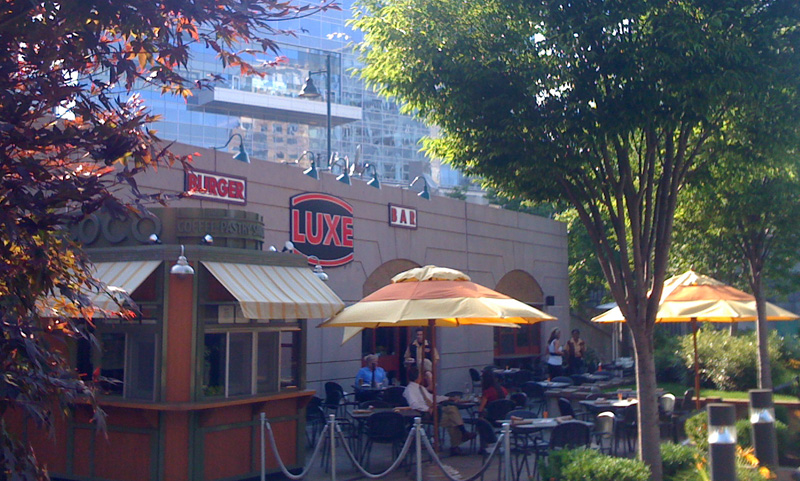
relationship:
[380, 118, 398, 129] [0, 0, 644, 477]
window on building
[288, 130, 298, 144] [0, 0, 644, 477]
window on building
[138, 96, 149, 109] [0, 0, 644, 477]
window on building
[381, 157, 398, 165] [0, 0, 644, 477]
window on building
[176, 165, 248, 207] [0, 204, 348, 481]
sign on small building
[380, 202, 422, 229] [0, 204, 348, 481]
sign on small building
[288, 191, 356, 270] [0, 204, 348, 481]
luxe sign on small building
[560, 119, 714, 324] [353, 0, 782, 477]
branches are on tree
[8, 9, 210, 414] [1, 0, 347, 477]
leaves are on tree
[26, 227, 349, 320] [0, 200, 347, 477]
awnings on small building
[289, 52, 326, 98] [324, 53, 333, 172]
light on light pole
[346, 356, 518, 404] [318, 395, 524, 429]
people on table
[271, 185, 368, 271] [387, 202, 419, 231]
luxe sign on sign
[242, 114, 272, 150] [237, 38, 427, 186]
window on building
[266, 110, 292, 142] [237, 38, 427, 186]
window on building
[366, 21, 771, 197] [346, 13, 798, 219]
part of tree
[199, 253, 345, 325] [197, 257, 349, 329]
awning has stripes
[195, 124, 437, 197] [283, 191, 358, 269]
lights for th sign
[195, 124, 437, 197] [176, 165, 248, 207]
lights for th sign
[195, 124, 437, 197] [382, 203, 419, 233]
lights for th sign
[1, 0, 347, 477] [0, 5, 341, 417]
tree has red leaves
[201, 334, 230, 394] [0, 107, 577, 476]
window on a building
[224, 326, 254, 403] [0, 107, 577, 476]
window on a building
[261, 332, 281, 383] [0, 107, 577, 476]
window on a building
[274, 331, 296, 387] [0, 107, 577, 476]
window on a building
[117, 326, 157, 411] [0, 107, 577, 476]
window on a building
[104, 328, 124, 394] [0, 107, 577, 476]
window on a building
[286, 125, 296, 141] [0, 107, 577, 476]
window on a building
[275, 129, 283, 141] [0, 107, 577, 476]
window on a building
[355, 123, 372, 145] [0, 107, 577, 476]
window on a building